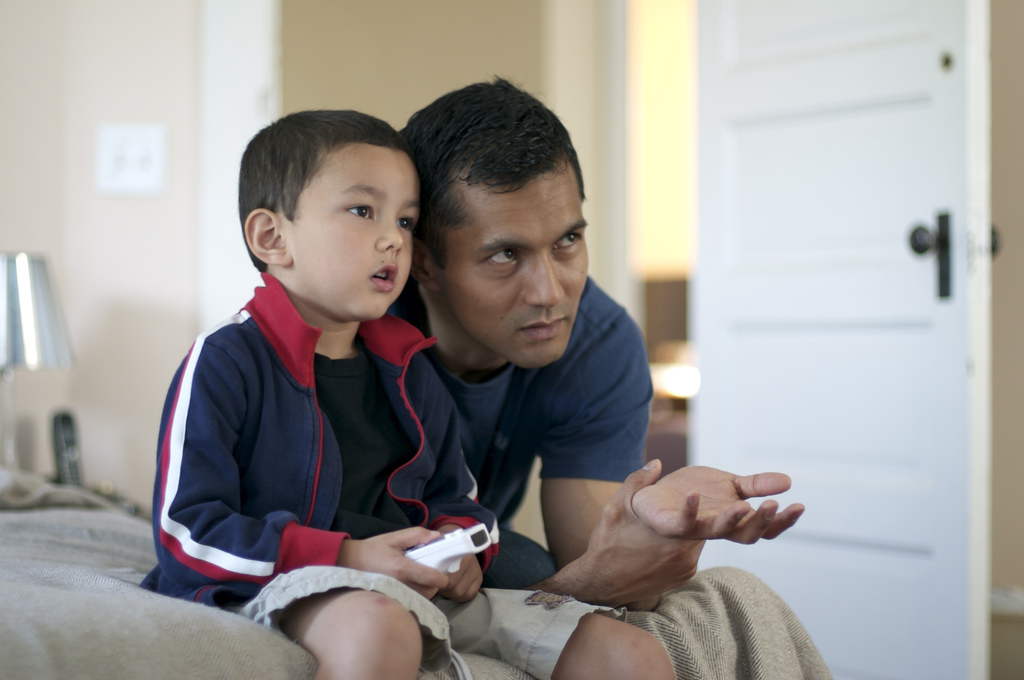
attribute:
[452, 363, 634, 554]
shirt — short sleeve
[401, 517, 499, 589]
remote — wii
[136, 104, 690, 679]
boy — young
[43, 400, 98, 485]
phone — cordless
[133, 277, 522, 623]
jacket — red, black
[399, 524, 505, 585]
remote — wii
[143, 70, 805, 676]
two guys — looking away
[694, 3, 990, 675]
door — white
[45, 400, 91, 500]
cordless phone — black and gray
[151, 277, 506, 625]
shirt — red white and blue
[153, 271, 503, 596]
jacket — blue, red, and white